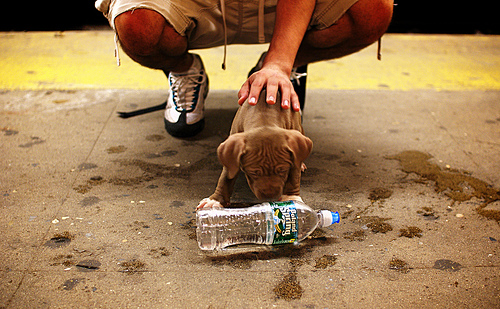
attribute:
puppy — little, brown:
[191, 85, 314, 214]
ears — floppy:
[218, 131, 313, 166]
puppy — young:
[202, 86, 312, 209]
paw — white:
[195, 190, 225, 207]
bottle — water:
[196, 203, 338, 250]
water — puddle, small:
[378, 142, 499, 227]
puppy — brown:
[203, 72, 332, 214]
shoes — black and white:
[113, 47, 349, 149]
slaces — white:
[175, 74, 218, 88]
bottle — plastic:
[173, 177, 388, 260]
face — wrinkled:
[216, 128, 311, 202]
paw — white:
[194, 191, 221, 216]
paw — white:
[273, 186, 305, 206]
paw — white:
[293, 157, 309, 174]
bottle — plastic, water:
[190, 196, 342, 256]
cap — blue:
[332, 211, 339, 222]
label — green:
[269, 200, 304, 246]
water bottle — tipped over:
[197, 199, 344, 256]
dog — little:
[194, 87, 314, 210]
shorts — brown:
[90, 0, 392, 75]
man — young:
[90, 1, 392, 132]